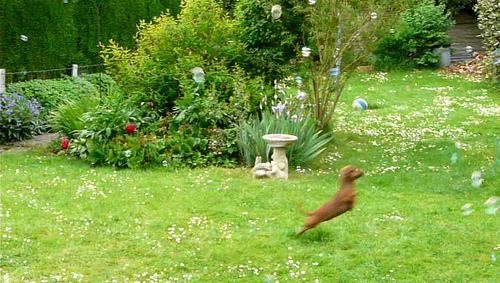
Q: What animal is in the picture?
A: A dog.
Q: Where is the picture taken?
A: A garden.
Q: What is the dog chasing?
A: Bubbles.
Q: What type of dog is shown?
A: Miniature brown.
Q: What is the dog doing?
A: Jumping.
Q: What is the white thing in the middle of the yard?
A: Bird bath.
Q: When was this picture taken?
A: Daytime.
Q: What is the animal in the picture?
A: A dog.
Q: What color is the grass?
A: Green.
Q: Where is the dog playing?
A: On the grass.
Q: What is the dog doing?
A: Jumping.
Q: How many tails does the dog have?
A: One.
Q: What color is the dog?
A: Brown.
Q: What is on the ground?
A: Grass.